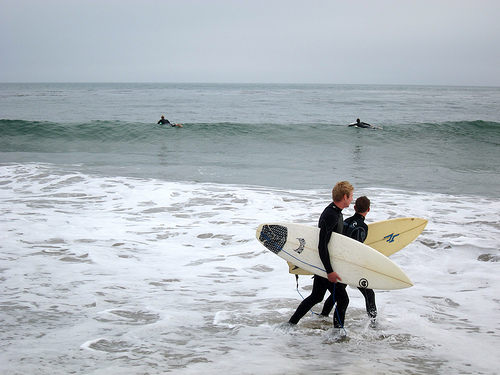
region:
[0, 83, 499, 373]
Grey ocean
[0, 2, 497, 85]
Grey skies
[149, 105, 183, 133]
An indistinct surfer paddling out to meet the waves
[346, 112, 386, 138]
Another surfer waiting for waves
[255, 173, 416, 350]
A blonde male surfer carrying his board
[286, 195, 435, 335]
A dark haired male surfer carrying his pale yellow surfboard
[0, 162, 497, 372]
White sea foam from a wave ascending the beach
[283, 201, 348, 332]
A black wetsuit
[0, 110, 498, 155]
A small, rolling ocean wave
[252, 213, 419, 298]
White surfboard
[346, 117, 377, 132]
surfer floating on a wave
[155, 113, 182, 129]
surfer floating on a wave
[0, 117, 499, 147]
wave in the ocean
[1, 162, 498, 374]
white foam on ocean water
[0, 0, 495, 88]
hazy sky above ocean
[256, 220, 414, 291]
white surfboard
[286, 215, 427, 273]
baige surfboard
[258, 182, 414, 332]
man in black wetsuit packing surfboard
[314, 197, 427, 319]
man in black wetsuit packing surfboard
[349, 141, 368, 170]
reflection of surfer on water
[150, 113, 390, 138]
two people in the ocean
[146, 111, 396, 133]
two people surfing in the ocean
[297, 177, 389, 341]
two people walking in the ocean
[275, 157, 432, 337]
two people carrying surf boards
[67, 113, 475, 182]
a wave in the ocean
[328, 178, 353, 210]
a man with blonde hair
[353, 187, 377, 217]
a man with brown hair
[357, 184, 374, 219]
a man with short hair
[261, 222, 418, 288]
a white surf board with a design on it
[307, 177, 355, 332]
a man wearing a wet suit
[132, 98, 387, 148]
two people on surfboards in ocean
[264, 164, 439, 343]
two men walking with surfboards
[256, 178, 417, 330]
man carrying a white surfboard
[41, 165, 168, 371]
white foam from crashing waves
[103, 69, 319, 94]
horizon where the ocean and sky meet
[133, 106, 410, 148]
two men on top of a small wave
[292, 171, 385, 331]
two men wearing black wet suits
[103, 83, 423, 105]
ocean calm behind wave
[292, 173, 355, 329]
man with short blonde hair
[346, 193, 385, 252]
man looking out at other surfers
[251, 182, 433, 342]
a couple with skate boards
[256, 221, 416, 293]
a white surf board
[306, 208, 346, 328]
a black wet suit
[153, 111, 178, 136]
a person surfing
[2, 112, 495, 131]
people on a wave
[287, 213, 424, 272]
a cream color surf board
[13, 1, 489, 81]
a gray cloudy sky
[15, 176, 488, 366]
white foam on the water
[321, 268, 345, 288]
a right hand of a man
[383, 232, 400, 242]
a symbol on a board